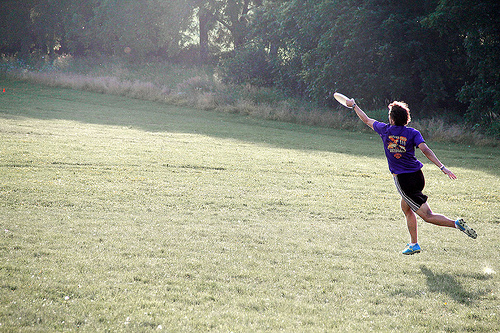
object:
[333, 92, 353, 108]
disk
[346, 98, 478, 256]
man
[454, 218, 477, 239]
cleats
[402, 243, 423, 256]
cleats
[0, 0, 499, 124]
woods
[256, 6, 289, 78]
tree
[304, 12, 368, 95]
tree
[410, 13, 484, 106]
tree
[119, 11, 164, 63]
tree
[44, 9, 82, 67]
tree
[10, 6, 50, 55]
tree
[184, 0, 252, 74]
tree